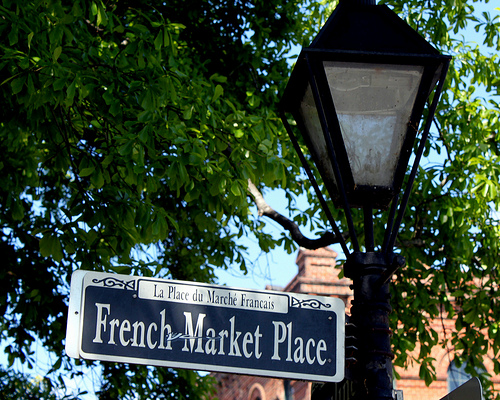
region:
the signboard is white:
[92, 268, 340, 388]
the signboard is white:
[112, 281, 262, 373]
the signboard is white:
[87, 188, 388, 382]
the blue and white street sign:
[59, 265, 362, 383]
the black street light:
[277, 7, 461, 398]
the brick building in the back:
[164, 237, 498, 397]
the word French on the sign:
[86, 296, 167, 351]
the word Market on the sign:
[180, 305, 260, 360]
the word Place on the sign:
[265, 315, 328, 365]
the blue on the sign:
[302, 310, 324, 333]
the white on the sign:
[140, 284, 153, 297]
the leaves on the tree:
[26, 133, 185, 235]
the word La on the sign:
[152, 284, 167, 301]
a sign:
[125, 267, 282, 375]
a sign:
[177, 205, 304, 389]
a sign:
[128, 231, 192, 339]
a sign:
[170, 284, 235, 368]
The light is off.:
[285, 15, 456, 230]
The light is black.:
[283, 15, 425, 217]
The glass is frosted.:
[309, 57, 404, 228]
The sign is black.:
[54, 247, 356, 375]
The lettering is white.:
[55, 272, 317, 397]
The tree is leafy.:
[50, 41, 243, 197]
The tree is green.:
[71, 39, 203, 169]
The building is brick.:
[289, 252, 337, 299]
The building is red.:
[286, 240, 337, 281]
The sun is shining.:
[55, 21, 497, 348]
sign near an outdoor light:
[50, 264, 365, 383]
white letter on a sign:
[86, 297, 115, 351]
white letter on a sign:
[101, 312, 122, 349]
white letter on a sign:
[119, 318, 131, 348]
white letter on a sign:
[129, 317, 146, 352]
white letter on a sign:
[142, 317, 159, 354]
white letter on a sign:
[155, 306, 177, 353]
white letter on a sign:
[178, 309, 206, 356]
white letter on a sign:
[265, 318, 288, 366]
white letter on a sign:
[227, 313, 242, 363]